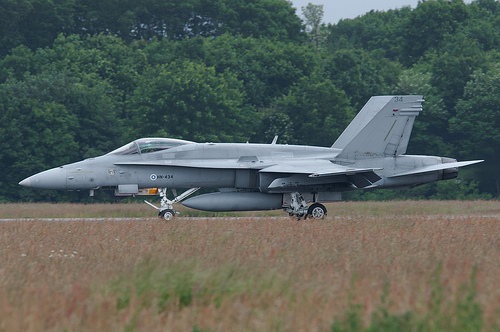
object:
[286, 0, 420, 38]
sky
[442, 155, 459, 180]
exhaust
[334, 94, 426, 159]
vertical stabalizer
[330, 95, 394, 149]
vertical stabalizer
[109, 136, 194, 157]
cockpit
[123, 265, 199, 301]
grass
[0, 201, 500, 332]
field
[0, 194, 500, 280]
ground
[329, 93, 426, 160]
grey tail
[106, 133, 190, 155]
enclosure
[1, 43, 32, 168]
forest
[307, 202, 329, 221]
wheel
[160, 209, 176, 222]
wheel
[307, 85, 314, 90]
leaves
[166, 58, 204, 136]
trees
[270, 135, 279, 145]
rudder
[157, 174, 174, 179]
numbering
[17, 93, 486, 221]
airplane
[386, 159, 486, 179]
propeller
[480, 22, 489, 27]
leaves